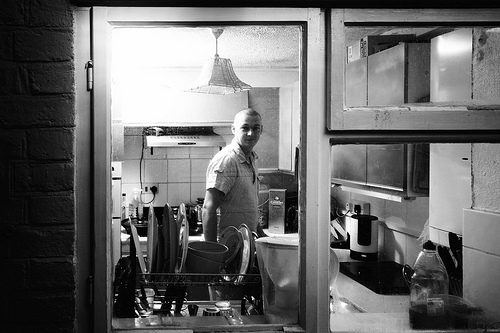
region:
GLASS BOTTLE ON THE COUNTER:
[407, 245, 454, 323]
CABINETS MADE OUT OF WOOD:
[379, 75, 396, 85]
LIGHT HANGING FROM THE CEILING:
[191, 55, 250, 95]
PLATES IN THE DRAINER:
[163, 205, 181, 270]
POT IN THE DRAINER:
[195, 238, 231, 278]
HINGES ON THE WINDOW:
[81, 59, 98, 93]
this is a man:
[174, 104, 316, 286]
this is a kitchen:
[81, 16, 455, 328]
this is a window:
[50, 23, 492, 325]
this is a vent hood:
[135, 116, 226, 156]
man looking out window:
[174, 71, 292, 300]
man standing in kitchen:
[91, 6, 461, 332]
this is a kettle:
[331, 191, 397, 267]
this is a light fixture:
[152, 20, 265, 108]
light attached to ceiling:
[164, 24, 268, 114]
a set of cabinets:
[270, 29, 422, 195]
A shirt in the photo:
[214, 147, 261, 228]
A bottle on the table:
[398, 232, 453, 323]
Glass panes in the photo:
[369, 42, 436, 106]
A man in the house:
[198, 101, 262, 219]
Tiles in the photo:
[157, 153, 186, 188]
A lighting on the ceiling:
[194, 58, 251, 101]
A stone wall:
[36, 61, 76, 185]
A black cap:
[420, 237, 440, 254]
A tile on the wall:
[450, 162, 470, 200]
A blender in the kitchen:
[346, 205, 376, 257]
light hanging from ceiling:
[178, 23, 254, 103]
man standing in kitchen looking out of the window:
[89, 97, 315, 332]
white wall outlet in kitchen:
[341, 195, 373, 220]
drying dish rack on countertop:
[130, 263, 265, 320]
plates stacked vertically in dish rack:
[140, 200, 192, 288]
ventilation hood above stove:
[135, 123, 228, 155]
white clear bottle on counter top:
[406, 235, 454, 331]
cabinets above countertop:
[328, 35, 430, 206]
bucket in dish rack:
[187, 233, 232, 285]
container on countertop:
[252, 226, 341, 321]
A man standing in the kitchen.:
[192, 92, 284, 257]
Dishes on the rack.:
[146, 215, 257, 289]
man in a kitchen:
[198, 102, 263, 282]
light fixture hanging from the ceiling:
[186, 28, 256, 100]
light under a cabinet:
[138, 126, 225, 153]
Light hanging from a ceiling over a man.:
[182, 24, 253, 98]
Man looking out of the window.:
[202, 108, 264, 239]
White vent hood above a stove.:
[141, 125, 226, 150]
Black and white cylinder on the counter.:
[348, 213, 382, 261]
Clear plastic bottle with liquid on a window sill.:
[411, 239, 451, 330]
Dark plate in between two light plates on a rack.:
[159, 202, 178, 276]